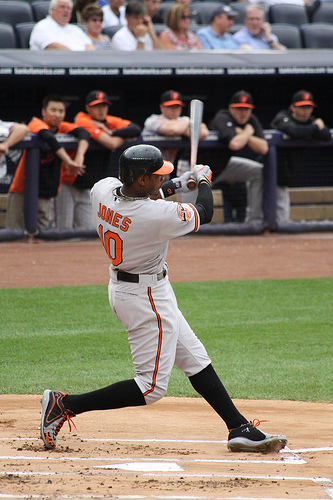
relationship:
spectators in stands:
[29, 0, 287, 55] [0, 1, 332, 49]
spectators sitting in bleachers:
[33, 0, 281, 46] [16, 12, 312, 199]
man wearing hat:
[39, 145, 287, 453] [115, 142, 177, 183]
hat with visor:
[115, 142, 177, 183] [149, 160, 174, 175]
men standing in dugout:
[0, 82, 332, 222] [1, 47, 331, 230]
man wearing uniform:
[73, 151, 269, 445] [87, 194, 210, 404]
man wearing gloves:
[39, 144, 290, 455] [167, 161, 217, 192]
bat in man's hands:
[179, 94, 215, 190] [174, 165, 215, 193]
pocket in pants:
[111, 288, 141, 306] [107, 284, 176, 373]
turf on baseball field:
[168, 397, 322, 447] [3, 281, 331, 487]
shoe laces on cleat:
[49, 410, 74, 436] [218, 421, 305, 461]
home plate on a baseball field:
[98, 456, 193, 484] [0, 238, 331, 499]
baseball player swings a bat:
[26, 88, 298, 438] [174, 93, 262, 195]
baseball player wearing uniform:
[41, 99, 289, 454] [84, 162, 225, 408]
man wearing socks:
[39, 144, 287, 454] [64, 360, 249, 427]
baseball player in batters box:
[13, 64, 329, 162] [2, 54, 331, 231]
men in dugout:
[0, 82, 332, 222] [2, 75, 332, 227]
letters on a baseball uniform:
[95, 198, 128, 233] [88, 176, 211, 406]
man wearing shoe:
[39, 144, 290, 455] [224, 418, 287, 453]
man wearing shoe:
[39, 144, 290, 455] [37, 388, 78, 449]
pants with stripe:
[103, 264, 217, 406] [133, 282, 169, 400]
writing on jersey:
[95, 200, 132, 264] [85, 181, 199, 277]